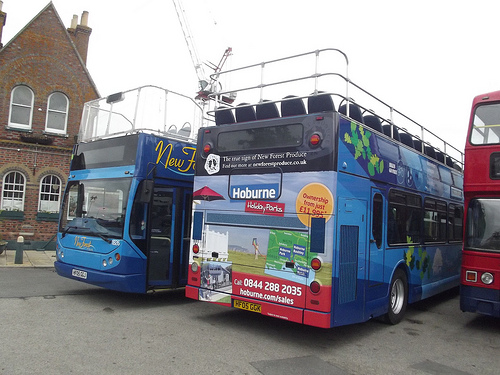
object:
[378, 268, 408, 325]
black tire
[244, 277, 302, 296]
white numbers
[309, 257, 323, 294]
lights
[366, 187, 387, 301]
blue door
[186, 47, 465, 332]
bus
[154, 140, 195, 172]
yellow writing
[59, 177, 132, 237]
large windshield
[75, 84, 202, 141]
windshield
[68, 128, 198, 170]
deck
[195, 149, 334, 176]
advertisement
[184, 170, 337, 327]
advertisement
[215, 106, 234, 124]
seat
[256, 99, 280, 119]
seat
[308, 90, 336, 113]
seat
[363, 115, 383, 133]
seat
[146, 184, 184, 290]
door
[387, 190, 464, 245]
window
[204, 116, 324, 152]
brake light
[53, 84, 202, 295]
bus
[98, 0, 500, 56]
clouds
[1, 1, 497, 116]
sky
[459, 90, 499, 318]
bus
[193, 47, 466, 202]
top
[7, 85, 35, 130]
window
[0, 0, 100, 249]
building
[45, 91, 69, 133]
window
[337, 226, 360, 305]
vent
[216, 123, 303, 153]
back window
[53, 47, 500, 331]
three buses